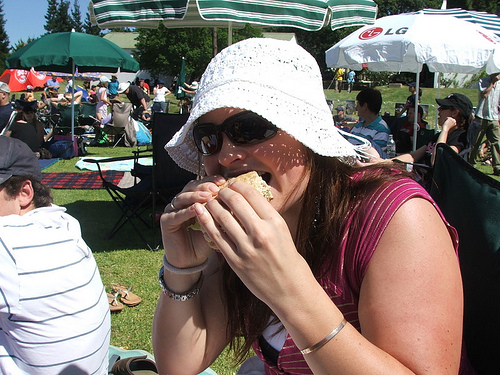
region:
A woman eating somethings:
[134, 35, 442, 372]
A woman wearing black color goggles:
[196, 106, 279, 161]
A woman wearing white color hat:
[158, 38, 365, 169]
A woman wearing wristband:
[160, 252, 206, 279]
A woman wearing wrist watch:
[155, 272, 214, 307]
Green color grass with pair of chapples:
[96, 247, 146, 320]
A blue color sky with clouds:
[7, 2, 32, 29]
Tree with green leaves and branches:
[0, 0, 79, 27]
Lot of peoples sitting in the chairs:
[8, 4, 497, 339]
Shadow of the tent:
[61, 188, 108, 237]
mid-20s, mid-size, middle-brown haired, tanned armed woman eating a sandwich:
[132, 25, 482, 373]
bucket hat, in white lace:
[140, 21, 374, 186]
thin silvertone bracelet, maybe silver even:
[292, 311, 354, 364]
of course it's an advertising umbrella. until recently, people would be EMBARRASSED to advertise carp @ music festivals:
[329, 12, 495, 79]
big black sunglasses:
[184, 102, 297, 177]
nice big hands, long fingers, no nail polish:
[160, 174, 315, 293]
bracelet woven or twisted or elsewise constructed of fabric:
[156, 255, 218, 281]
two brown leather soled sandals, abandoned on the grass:
[102, 271, 147, 320]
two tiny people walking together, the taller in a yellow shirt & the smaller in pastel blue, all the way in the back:
[327, 61, 364, 97]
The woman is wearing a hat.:
[173, 34, 364, 155]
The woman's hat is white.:
[167, 30, 352, 147]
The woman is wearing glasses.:
[176, 97, 300, 160]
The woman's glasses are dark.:
[179, 98, 279, 146]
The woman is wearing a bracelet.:
[287, 309, 359, 358]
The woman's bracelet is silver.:
[290, 315, 357, 357]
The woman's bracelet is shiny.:
[282, 313, 362, 367]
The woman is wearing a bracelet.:
[149, 266, 210, 313]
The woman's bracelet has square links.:
[142, 265, 207, 313]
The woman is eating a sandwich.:
[165, 159, 302, 244]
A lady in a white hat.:
[154, 34, 464, 374]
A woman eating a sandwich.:
[148, 35, 466, 374]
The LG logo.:
[358, 24, 408, 41]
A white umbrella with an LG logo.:
[322, 10, 499, 75]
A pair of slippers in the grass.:
[105, 282, 142, 312]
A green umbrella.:
[3, 26, 143, 138]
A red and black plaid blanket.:
[36, 168, 122, 191]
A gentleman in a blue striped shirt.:
[337, 83, 397, 151]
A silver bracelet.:
[295, 315, 357, 355]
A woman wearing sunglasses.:
[154, 35, 465, 373]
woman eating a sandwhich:
[152, 37, 464, 374]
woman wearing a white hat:
[150, 38, 465, 370]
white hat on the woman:
[162, 38, 358, 175]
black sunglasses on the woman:
[192, 110, 276, 157]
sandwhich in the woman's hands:
[186, 171, 273, 240]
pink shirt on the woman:
[235, 166, 459, 374]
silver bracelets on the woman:
[151, 262, 351, 359]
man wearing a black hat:
[1, 136, 110, 374]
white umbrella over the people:
[324, 17, 497, 69]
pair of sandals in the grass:
[107, 284, 142, 310]